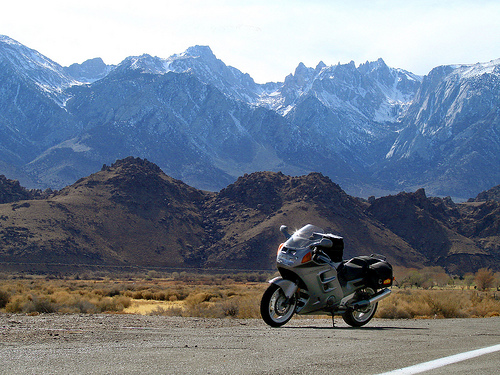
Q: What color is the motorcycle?
A: Gray.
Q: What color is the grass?
A: Brown.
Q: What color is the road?
A: Gray.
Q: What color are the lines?
A: White.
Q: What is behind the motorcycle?
A: Dirt hills.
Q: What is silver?
A: Motorcycle.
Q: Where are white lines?
A: Asphalt.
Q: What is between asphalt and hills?
A: Grassy area.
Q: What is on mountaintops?
A: Snow.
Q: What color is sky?
A: Pale blue.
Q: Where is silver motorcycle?
A: Side of road.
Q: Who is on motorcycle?
A: No One.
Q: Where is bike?
A: Side of road.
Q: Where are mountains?
A: In distance.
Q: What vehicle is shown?
A: A motorcycle.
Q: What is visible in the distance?
A: Mountains.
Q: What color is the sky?
A: White.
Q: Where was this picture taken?
A: A parking lot.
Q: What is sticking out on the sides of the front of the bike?
A: Mirrors.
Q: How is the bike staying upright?
A: Kickstand.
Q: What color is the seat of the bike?
A: Black.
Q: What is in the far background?
A: Mountains.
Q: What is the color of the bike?
A: Black and silver.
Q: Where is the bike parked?
A: Shoulder of the highway.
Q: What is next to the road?
A: Grass.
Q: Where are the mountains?
A: Background.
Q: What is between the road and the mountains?
A: Dirt hills.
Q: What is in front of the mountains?
A: Hills.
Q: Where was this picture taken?
A: In the mountains.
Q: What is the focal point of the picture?
A: The motorcycle.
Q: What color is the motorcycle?
A: Silver.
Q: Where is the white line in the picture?
A: The right side.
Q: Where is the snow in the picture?
A: On top of the highest mountains.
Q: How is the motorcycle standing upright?
A: The kickstand.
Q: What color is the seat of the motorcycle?
A: Black.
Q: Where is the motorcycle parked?
A: On the side of the road.